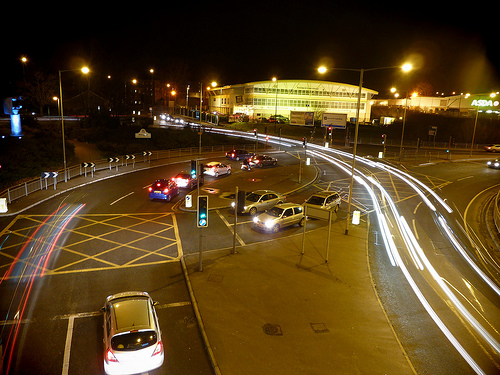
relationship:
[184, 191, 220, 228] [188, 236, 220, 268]
stop light on pole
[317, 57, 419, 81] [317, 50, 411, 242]
lights on pole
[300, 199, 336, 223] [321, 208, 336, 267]
sign on pole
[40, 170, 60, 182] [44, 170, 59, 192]
sign on pole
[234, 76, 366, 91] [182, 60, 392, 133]
roof of building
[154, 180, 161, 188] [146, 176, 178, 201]
light in car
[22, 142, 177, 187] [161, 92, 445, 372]
signs indicating right turn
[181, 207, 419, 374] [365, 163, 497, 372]
median separating lane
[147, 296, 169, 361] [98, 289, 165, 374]
side of car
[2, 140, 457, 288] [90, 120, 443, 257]
lines in intersection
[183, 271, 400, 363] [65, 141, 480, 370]
concrete in middle of intersection